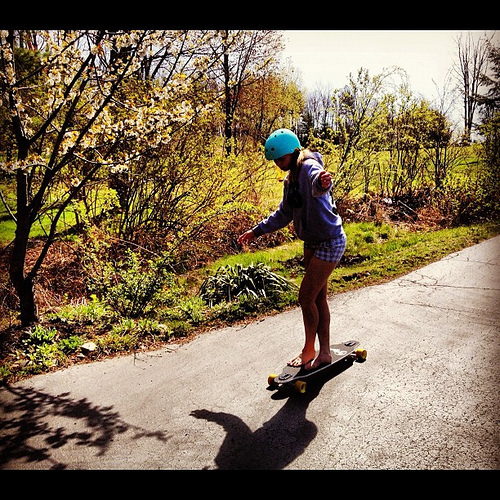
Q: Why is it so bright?
A: Sunny.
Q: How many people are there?
A: One.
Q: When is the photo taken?
A: Day time.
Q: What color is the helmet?
A: Blue.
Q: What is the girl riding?
A: The skateboard.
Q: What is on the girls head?
A: The helmet.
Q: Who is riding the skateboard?
A: The girl.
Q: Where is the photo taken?
A: At a park.